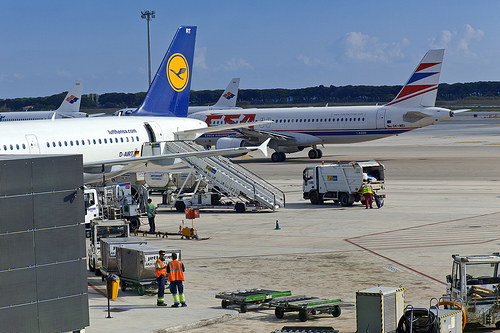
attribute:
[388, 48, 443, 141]
tail — blue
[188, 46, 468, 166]
plane — commercial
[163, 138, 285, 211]
steps — up, white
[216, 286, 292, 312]
trailer — empty, green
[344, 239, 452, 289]
line — red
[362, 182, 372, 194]
vest — yellow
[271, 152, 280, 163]
wheel — black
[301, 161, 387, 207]
truck — white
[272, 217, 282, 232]
cone — blue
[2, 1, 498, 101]
sky — cloudy, blue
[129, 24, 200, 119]
fin — blue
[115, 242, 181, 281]
container — grey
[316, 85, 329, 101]
tree — behind